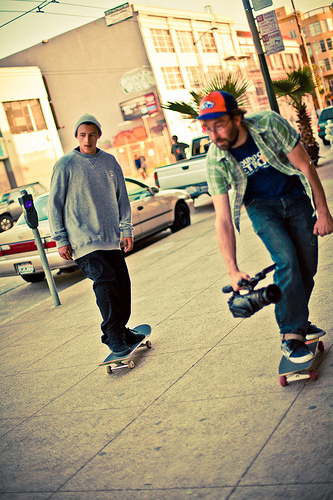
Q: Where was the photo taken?
A: It was taken at the sidewalk.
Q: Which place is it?
A: It is a sidewalk.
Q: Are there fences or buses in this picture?
A: No, there are no fences or buses.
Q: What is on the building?
A: The sign is on the building.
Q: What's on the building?
A: The sign is on the building.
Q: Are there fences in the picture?
A: No, there are no fences.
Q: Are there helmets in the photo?
A: No, there are no helmets.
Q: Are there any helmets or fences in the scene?
A: No, there are no helmets or fences.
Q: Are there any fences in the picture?
A: No, there are no fences.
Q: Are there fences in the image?
A: No, there are no fences.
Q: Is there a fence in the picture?
A: No, there are no fences.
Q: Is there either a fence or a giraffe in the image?
A: No, there are no fences or giraffes.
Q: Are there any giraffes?
A: No, there are no giraffes.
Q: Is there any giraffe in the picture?
A: No, there are no giraffes.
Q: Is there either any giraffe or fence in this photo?
A: No, there are no giraffes or fences.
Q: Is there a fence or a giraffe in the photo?
A: No, there are no giraffes or fences.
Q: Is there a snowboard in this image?
A: No, there are no snowboards.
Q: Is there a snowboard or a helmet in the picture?
A: No, there are no snowboards or helmets.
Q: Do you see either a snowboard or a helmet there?
A: No, there are no snowboards or helmets.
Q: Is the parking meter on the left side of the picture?
A: Yes, the parking meter is on the left of the image.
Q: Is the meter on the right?
A: No, the meter is on the left of the image.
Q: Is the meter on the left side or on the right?
A: The meter is on the left of the image.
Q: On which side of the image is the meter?
A: The meter is on the left of the image.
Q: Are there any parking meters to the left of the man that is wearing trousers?
A: Yes, there is a parking meter to the left of the man.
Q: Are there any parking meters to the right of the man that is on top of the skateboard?
A: No, the parking meter is to the left of the man.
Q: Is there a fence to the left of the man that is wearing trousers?
A: No, there is a parking meter to the left of the man.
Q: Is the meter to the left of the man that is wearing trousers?
A: Yes, the meter is to the left of the man.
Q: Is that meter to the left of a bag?
A: No, the meter is to the left of the man.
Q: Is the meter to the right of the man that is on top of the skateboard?
A: No, the meter is to the left of the man.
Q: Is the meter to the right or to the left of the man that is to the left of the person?
A: The meter is to the left of the man.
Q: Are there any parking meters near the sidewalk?
A: Yes, there is a parking meter near the sidewalk.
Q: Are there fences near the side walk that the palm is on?
A: No, there is a parking meter near the side walk.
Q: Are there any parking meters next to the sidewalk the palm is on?
A: Yes, there is a parking meter next to the sidewalk.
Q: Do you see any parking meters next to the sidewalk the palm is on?
A: Yes, there is a parking meter next to the sidewalk.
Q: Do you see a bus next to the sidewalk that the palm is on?
A: No, there is a parking meter next to the sidewalk.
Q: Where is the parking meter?
A: The parking meter is on the sidewalk.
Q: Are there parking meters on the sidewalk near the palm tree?
A: Yes, there is a parking meter on the sidewalk.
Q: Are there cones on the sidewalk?
A: No, there is a parking meter on the sidewalk.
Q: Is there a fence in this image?
A: No, there are no fences.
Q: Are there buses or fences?
A: No, there are no fences or buses.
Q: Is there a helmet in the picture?
A: No, there are no helmets.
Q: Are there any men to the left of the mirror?
A: Yes, there is a man to the left of the mirror.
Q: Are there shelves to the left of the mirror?
A: No, there is a man to the left of the mirror.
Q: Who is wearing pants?
A: The man is wearing pants.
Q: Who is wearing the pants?
A: The man is wearing pants.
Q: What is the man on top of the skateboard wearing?
A: The man is wearing pants.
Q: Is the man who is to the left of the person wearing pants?
A: Yes, the man is wearing pants.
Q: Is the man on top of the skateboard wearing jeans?
A: No, the man is wearing pants.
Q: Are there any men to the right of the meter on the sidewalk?
A: Yes, there is a man to the right of the parking meter.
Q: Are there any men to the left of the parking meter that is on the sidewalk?
A: No, the man is to the right of the parking meter.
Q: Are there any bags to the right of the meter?
A: No, there is a man to the right of the meter.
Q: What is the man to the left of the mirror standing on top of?
A: The man is standing on top of the skateboard.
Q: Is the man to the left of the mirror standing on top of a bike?
A: No, the man is standing on top of the skateboard.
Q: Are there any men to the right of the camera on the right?
A: No, the man is to the left of the camera.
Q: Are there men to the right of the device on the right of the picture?
A: No, the man is to the left of the camera.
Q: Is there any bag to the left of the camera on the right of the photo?
A: No, there is a man to the left of the camera.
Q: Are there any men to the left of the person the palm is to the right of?
A: Yes, there is a man to the left of the person.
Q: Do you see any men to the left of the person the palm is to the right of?
A: Yes, there is a man to the left of the person.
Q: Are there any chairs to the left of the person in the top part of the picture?
A: No, there is a man to the left of the person.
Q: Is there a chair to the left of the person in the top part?
A: No, there is a man to the left of the person.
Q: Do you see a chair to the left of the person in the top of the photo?
A: No, there is a man to the left of the person.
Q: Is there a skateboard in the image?
A: Yes, there is a skateboard.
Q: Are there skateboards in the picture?
A: Yes, there is a skateboard.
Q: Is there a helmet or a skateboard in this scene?
A: Yes, there is a skateboard.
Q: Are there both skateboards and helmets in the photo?
A: No, there is a skateboard but no helmets.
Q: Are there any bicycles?
A: No, there are no bicycles.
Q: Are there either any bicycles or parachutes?
A: No, there are no bicycles or parachutes.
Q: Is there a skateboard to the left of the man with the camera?
A: Yes, there is a skateboard to the left of the man.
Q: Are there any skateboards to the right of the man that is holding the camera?
A: No, the skateboard is to the left of the man.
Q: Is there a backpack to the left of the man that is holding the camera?
A: No, there is a skateboard to the left of the man.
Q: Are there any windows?
A: Yes, there are windows.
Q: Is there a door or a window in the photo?
A: Yes, there are windows.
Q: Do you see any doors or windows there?
A: Yes, there are windows.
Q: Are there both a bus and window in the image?
A: No, there are windows but no buses.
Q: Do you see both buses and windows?
A: No, there are windows but no buses.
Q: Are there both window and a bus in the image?
A: No, there are windows but no buses.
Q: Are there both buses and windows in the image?
A: No, there are windows but no buses.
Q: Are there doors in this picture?
A: No, there are no doors.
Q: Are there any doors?
A: No, there are no doors.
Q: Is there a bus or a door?
A: No, there are no doors or buses.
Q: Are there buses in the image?
A: No, there are no buses.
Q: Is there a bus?
A: No, there are no buses.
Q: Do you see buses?
A: No, there are no buses.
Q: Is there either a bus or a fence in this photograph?
A: No, there are no buses or fences.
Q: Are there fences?
A: No, there are no fences.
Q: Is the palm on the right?
A: Yes, the palm is on the right of the image.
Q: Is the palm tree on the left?
A: No, the palm tree is on the right of the image.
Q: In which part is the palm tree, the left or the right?
A: The palm tree is on the right of the image.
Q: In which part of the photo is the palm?
A: The palm is on the right of the image.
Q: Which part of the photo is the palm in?
A: The palm is on the right of the image.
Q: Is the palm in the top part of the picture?
A: Yes, the palm is in the top of the image.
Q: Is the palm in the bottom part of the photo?
A: No, the palm is in the top of the image.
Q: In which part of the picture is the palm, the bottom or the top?
A: The palm is in the top of the image.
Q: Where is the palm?
A: The palm is on the sidewalk.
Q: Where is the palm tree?
A: The palm is on the sidewalk.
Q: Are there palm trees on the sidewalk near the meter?
A: Yes, there is a palm tree on the sidewalk.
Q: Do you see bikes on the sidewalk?
A: No, there is a palm tree on the sidewalk.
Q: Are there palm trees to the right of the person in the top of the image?
A: Yes, there is a palm tree to the right of the person.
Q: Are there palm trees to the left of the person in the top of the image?
A: No, the palm tree is to the right of the person.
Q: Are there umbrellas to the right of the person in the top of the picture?
A: No, there is a palm tree to the right of the person.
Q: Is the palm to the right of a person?
A: Yes, the palm is to the right of a person.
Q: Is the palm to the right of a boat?
A: No, the palm is to the right of a person.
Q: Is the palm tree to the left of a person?
A: No, the palm tree is to the right of a person.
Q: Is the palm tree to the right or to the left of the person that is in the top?
A: The palm tree is to the right of the person.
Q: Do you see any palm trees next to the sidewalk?
A: Yes, there is a palm tree next to the sidewalk.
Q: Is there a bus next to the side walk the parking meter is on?
A: No, there is a palm tree next to the sidewalk.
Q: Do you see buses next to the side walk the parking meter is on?
A: No, there is a palm tree next to the sidewalk.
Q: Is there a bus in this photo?
A: No, there are no buses.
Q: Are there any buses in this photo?
A: No, there are no buses.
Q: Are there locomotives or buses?
A: No, there are no buses or locomotives.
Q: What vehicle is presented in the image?
A: The vehicle is a car.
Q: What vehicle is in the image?
A: The vehicle is a car.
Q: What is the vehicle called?
A: The vehicle is a car.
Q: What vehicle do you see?
A: The vehicle is a car.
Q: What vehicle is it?
A: The vehicle is a car.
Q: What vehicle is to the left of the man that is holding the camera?
A: The vehicle is a car.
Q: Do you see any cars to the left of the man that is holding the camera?
A: Yes, there is a car to the left of the man.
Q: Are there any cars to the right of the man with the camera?
A: No, the car is to the left of the man.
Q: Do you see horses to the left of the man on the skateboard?
A: No, there is a car to the left of the man.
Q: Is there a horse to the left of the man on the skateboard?
A: No, there is a car to the left of the man.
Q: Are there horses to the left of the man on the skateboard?
A: No, there is a car to the left of the man.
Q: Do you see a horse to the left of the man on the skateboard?
A: No, there is a car to the left of the man.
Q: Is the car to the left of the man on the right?
A: Yes, the car is to the left of the man.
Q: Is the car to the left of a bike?
A: No, the car is to the left of the man.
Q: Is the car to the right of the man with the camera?
A: No, the car is to the left of the man.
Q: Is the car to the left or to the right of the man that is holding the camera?
A: The car is to the left of the man.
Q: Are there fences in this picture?
A: No, there are no fences.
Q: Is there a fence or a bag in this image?
A: No, there are no fences or bags.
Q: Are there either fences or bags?
A: No, there are no fences or bags.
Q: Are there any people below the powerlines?
A: Yes, there is a person below the powerlines.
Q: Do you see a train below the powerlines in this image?
A: No, there is a person below the powerlines.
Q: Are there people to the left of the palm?
A: Yes, there is a person to the left of the palm.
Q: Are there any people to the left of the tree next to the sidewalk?
A: Yes, there is a person to the left of the palm.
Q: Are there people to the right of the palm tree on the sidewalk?
A: No, the person is to the left of the palm tree.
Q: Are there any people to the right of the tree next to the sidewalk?
A: No, the person is to the left of the palm tree.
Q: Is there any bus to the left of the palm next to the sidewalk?
A: No, there is a person to the left of the palm tree.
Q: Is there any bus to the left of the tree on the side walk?
A: No, there is a person to the left of the palm tree.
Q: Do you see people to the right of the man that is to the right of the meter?
A: Yes, there is a person to the right of the man.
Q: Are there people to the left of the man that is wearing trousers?
A: No, the person is to the right of the man.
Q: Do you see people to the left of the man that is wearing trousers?
A: No, the person is to the right of the man.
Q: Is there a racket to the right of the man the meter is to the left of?
A: No, there is a person to the right of the man.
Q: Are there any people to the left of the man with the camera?
A: Yes, there is a person to the left of the man.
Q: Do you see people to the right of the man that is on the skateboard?
A: No, the person is to the left of the man.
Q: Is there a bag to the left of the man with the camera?
A: No, there is a person to the left of the man.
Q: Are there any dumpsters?
A: No, there are no dumpsters.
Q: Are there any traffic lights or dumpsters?
A: No, there are no dumpsters or traffic lights.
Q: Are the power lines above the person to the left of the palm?
A: Yes, the power lines are above the person.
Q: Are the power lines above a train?
A: No, the power lines are above the person.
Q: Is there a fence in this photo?
A: No, there are no fences.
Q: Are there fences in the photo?
A: No, there are no fences.